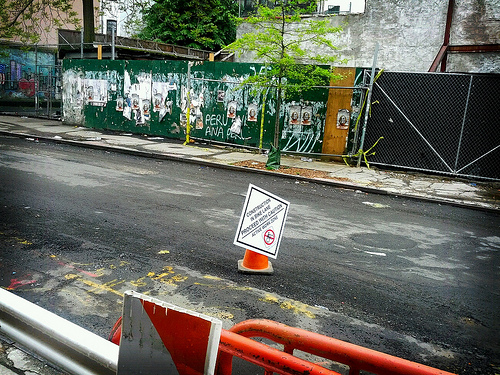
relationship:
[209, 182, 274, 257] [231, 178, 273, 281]
sign on traffic cone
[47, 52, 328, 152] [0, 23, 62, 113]
green boards with graffiti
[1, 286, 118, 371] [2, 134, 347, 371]
railing on side of street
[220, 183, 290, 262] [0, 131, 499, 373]
sign in road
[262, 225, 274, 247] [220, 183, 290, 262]
posting on sign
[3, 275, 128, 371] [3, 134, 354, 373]
gaurd rail on side of road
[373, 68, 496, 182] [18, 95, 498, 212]
fence along side walk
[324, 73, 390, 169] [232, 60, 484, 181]
tape hanging from fence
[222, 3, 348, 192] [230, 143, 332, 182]
tree in mulch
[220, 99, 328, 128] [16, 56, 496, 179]
posters on fence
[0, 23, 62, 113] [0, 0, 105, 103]
graffiti on side of building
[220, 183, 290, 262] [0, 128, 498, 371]
sign in street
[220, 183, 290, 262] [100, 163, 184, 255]
sign in street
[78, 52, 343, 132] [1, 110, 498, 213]
wall in sidewalk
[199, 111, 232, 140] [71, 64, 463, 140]
tagging on fence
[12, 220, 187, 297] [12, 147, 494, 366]
marking on street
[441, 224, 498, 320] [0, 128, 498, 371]
water on street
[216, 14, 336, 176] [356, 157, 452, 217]
folage middle sidewalk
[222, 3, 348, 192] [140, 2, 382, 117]
tree full leaves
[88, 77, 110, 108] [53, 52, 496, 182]
poster lining fence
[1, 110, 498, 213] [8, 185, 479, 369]
sidewalk among project